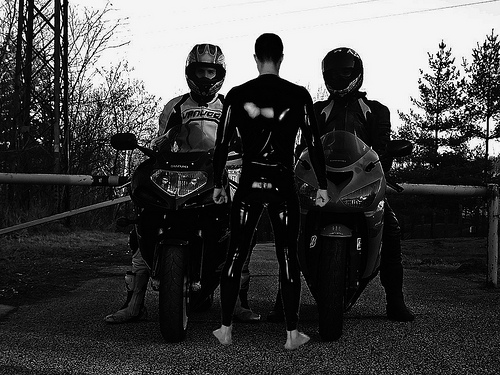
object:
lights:
[149, 163, 211, 198]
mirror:
[108, 130, 140, 150]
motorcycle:
[100, 125, 261, 340]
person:
[296, 46, 418, 326]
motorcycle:
[276, 129, 414, 335]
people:
[103, 31, 415, 352]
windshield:
[293, 143, 380, 186]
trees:
[1, 0, 498, 233]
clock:
[210, 28, 311, 345]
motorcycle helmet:
[320, 44, 364, 95]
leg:
[211, 196, 265, 346]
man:
[310, 48, 417, 323]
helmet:
[320, 47, 363, 97]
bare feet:
[212, 326, 310, 350]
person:
[103, 42, 262, 330]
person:
[208, 28, 331, 350]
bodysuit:
[208, 72, 324, 333]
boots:
[102, 241, 165, 324]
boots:
[381, 231, 413, 326]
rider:
[101, 37, 234, 336]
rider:
[297, 47, 414, 323]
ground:
[411, 163, 482, 216]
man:
[210, 31, 314, 352]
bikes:
[107, 127, 416, 342]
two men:
[100, 33, 417, 324]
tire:
[157, 245, 199, 336]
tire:
[315, 220, 355, 338]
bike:
[111, 132, 220, 337]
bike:
[290, 127, 413, 328]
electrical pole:
[10, 1, 74, 227]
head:
[253, 33, 285, 66]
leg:
[271, 205, 308, 350]